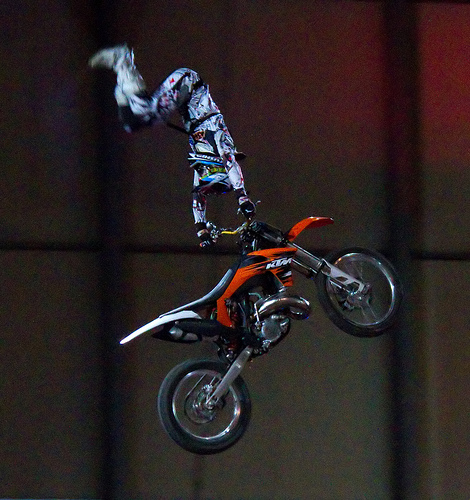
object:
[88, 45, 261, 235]
rider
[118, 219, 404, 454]
motorbike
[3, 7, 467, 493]
air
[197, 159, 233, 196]
helmet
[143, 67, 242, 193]
uniform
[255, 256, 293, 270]
logo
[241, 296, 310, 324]
exhaust pipe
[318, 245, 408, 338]
front wheel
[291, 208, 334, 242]
front fender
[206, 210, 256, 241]
handlebars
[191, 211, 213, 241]
hands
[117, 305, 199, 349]
tail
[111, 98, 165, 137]
knees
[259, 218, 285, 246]
lights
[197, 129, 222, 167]
person image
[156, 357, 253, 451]
lower wheel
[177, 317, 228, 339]
points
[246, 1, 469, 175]
background patch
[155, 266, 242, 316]
seat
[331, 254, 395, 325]
spokes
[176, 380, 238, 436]
spokes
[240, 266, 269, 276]
trim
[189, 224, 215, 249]
glove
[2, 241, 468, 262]
large line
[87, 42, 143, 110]
boots